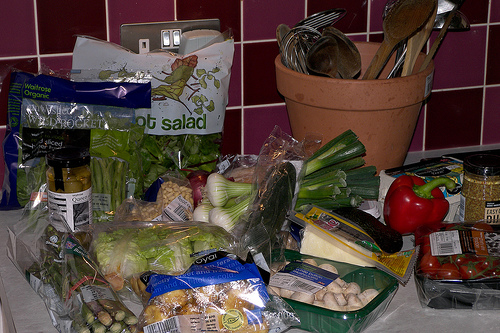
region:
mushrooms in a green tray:
[262, 250, 399, 330]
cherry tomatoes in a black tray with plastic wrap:
[415, 222, 495, 310]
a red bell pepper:
[381, 172, 451, 226]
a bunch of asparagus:
[2, 200, 140, 332]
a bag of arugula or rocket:
[15, 75, 150, 207]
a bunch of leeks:
[192, 128, 378, 228]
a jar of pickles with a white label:
[49, 150, 94, 230]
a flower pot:
[275, 40, 432, 163]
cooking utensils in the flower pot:
[275, 2, 465, 74]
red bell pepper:
[383, 172, 457, 237]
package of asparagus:
[8, 184, 140, 331]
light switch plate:
[121, 18, 219, 54]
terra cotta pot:
[273, 45, 432, 173]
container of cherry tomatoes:
[413, 220, 498, 313]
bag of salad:
[71, 34, 233, 196]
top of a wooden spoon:
[305, 37, 340, 74]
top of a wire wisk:
[277, 25, 317, 70]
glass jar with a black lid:
[461, 157, 497, 227]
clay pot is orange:
[264, 41, 460, 177]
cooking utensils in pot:
[253, 2, 442, 181]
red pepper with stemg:
[398, 179, 475, 238]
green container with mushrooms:
[230, 241, 389, 330]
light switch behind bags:
[118, 17, 232, 64]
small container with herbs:
[441, 153, 497, 228]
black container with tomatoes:
[425, 222, 492, 311]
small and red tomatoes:
[430, 227, 492, 304]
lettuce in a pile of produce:
[90, 219, 237, 278]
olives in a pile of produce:
[45, 145, 96, 238]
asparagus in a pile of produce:
[24, 220, 139, 330]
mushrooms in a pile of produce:
[262, 246, 402, 330]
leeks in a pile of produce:
[192, 129, 382, 231]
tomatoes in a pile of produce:
[414, 220, 499, 308]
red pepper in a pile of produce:
[383, 169, 463, 236]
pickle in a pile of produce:
[240, 157, 300, 265]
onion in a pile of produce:
[184, 168, 234, 207]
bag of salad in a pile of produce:
[73, 33, 239, 197]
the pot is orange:
[273, 31, 438, 170]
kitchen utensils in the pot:
[265, 2, 469, 170]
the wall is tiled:
[1, 2, 498, 192]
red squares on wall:
[1, 0, 498, 205]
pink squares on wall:
[1, 2, 498, 202]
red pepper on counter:
[380, 170, 460, 235]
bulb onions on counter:
[191, 127, 381, 233]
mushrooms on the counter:
[250, 240, 395, 325]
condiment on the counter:
[459, 149, 498, 225]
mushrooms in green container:
[258, 243, 403, 331]